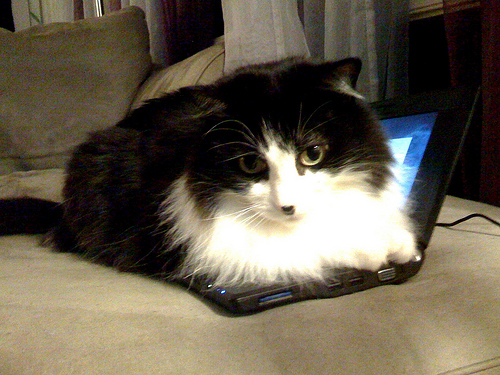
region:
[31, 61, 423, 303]
cat is black and white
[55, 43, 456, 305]
cat sitting on a laptop.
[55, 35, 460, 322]
precious cat sitting on a laptop.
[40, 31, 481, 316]
beautiful cat sitting on a laptop.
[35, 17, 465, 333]
attractive cat sitting on a laptop.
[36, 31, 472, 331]
adorable cat sitting on a laptop.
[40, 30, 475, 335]
cat smothering keys of a laptop.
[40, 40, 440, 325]
cute cat smothering keys of a laptop.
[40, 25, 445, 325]
cuddly cat smothering keys of a laptop.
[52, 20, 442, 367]
attractive cat smothering keys of a laptop.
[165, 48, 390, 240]
head of a cat.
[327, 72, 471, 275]
laptop screen is blue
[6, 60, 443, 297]
A black and white cat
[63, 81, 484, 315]
A cat on a laptop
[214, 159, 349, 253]
A cat with a black nose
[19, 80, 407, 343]
A cat and a laptop on a chair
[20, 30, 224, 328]
A beige chair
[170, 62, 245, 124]
The right ear of a cat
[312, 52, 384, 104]
The left ear of a cat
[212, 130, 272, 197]
The right eye of a cat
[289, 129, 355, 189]
The left eye of a cat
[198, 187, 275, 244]
The whiskers of a cat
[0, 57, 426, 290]
black and white cat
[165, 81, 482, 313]
small black laptop on coach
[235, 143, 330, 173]
yellow eyes of cat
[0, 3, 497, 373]
light beige coach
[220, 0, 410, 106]
Sheer white curtains in background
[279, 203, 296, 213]
black nose of cat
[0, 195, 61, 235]
furry tail of cat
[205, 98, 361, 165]
long whiskers of cat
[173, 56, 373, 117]
furry ears of cat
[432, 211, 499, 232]
narrow black cord